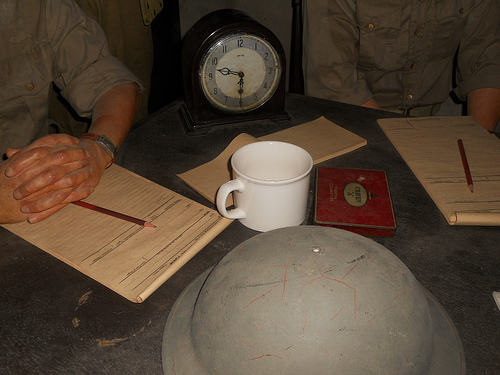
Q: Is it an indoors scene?
A: Yes, it is indoors.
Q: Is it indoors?
A: Yes, it is indoors.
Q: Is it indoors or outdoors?
A: It is indoors.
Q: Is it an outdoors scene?
A: No, it is indoors.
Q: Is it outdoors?
A: No, it is indoors.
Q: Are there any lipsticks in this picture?
A: No, there are no lipsticks.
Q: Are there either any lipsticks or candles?
A: No, there are no lipsticks or candles.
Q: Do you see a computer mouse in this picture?
A: No, there are no computer mice.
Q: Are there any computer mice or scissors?
A: No, there are no computer mice or scissors.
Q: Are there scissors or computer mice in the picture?
A: No, there are no computer mice or scissors.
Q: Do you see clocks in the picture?
A: Yes, there is a clock.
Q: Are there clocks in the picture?
A: Yes, there is a clock.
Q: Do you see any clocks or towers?
A: Yes, there is a clock.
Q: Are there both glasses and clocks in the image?
A: No, there is a clock but no glasses.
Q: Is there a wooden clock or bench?
A: Yes, there is a wood clock.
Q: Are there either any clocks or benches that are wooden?
A: Yes, the clock is wooden.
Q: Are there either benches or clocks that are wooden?
A: Yes, the clock is wooden.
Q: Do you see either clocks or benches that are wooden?
A: Yes, the clock is wooden.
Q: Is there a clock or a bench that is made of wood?
A: Yes, the clock is made of wood.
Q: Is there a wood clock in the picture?
A: Yes, there is a wood clock.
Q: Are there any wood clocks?
A: Yes, there is a wood clock.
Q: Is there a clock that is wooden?
A: Yes, there is a clock that is wooden.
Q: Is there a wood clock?
A: Yes, there is a clock that is made of wood.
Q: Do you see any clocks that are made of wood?
A: Yes, there is a clock that is made of wood.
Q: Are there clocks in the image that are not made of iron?
A: Yes, there is a clock that is made of wood.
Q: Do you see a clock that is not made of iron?
A: Yes, there is a clock that is made of wood.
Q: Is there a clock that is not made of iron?
A: Yes, there is a clock that is made of wood.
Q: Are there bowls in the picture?
A: No, there are no bowls.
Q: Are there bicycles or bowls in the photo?
A: No, there are no bowls or bicycles.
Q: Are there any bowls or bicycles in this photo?
A: No, there are no bowls or bicycles.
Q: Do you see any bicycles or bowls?
A: No, there are no bowls or bicycles.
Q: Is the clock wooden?
A: Yes, the clock is wooden.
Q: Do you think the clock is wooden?
A: Yes, the clock is wooden.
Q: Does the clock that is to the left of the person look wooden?
A: Yes, the clock is wooden.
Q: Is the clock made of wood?
A: Yes, the clock is made of wood.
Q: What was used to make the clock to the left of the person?
A: The clock is made of wood.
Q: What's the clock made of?
A: The clock is made of wood.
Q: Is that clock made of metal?
A: No, the clock is made of wood.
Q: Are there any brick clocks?
A: No, there is a clock but it is made of wood.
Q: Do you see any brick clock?
A: No, there is a clock but it is made of wood.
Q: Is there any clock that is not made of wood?
A: No, there is a clock but it is made of wood.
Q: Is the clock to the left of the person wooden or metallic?
A: The clock is wooden.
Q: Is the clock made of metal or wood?
A: The clock is made of wood.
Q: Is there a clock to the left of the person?
A: Yes, there is a clock to the left of the person.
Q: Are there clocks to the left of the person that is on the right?
A: Yes, there is a clock to the left of the person.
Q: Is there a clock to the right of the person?
A: No, the clock is to the left of the person.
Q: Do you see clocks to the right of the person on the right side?
A: No, the clock is to the left of the person.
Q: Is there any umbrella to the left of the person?
A: No, there is a clock to the left of the person.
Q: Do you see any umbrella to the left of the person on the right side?
A: No, there is a clock to the left of the person.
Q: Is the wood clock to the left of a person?
A: Yes, the clock is to the left of a person.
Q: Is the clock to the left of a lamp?
A: No, the clock is to the left of a person.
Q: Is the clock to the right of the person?
A: No, the clock is to the left of the person.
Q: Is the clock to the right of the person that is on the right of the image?
A: No, the clock is to the left of the person.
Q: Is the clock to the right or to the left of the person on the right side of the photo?
A: The clock is to the left of the person.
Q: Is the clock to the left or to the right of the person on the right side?
A: The clock is to the left of the person.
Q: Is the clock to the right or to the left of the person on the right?
A: The clock is to the left of the person.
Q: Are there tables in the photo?
A: Yes, there is a table.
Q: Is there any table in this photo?
A: Yes, there is a table.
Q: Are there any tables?
A: Yes, there is a table.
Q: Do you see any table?
A: Yes, there is a table.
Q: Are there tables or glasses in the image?
A: Yes, there is a table.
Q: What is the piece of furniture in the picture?
A: The piece of furniture is a table.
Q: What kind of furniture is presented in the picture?
A: The furniture is a table.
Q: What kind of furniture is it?
A: The piece of furniture is a table.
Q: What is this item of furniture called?
A: This is a table.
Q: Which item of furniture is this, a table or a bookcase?
A: This is a table.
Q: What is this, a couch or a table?
A: This is a table.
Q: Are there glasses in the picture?
A: No, there are no glasses.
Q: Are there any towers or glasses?
A: No, there are no glasses or towers.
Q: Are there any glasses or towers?
A: No, there are no glasses or towers.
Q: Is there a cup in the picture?
A: Yes, there is a cup.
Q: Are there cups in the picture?
A: Yes, there is a cup.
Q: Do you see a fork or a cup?
A: Yes, there is a cup.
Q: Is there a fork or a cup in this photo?
A: Yes, there is a cup.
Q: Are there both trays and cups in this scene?
A: No, there is a cup but no trays.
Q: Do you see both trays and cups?
A: No, there is a cup but no trays.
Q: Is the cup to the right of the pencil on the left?
A: Yes, the cup is to the right of the pencil.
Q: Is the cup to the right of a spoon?
A: No, the cup is to the right of the pencil.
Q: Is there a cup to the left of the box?
A: Yes, there is a cup to the left of the box.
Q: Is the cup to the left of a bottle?
A: No, the cup is to the left of the box.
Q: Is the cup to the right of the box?
A: No, the cup is to the left of the box.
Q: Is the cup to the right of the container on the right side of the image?
A: No, the cup is to the left of the box.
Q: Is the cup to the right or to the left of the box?
A: The cup is to the left of the box.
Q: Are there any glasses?
A: No, there are no glasses.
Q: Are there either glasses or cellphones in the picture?
A: No, there are no glasses or cellphones.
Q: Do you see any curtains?
A: No, there are no curtains.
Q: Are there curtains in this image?
A: No, there are no curtains.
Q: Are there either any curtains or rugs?
A: No, there are no curtains or rugs.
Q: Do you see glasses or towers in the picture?
A: No, there are no glasses or towers.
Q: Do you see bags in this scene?
A: No, there are no bags.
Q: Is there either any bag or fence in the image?
A: No, there are no bags or fences.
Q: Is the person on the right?
A: Yes, the person is on the right of the image.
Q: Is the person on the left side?
A: No, the person is on the right of the image.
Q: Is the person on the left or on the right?
A: The person is on the right of the image.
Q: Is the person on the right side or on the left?
A: The person is on the right of the image.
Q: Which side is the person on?
A: The person is on the right of the image.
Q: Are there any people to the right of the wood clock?
A: Yes, there is a person to the right of the clock.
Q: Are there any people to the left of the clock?
A: No, the person is to the right of the clock.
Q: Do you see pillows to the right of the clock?
A: No, there is a person to the right of the clock.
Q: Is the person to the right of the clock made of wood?
A: Yes, the person is to the right of the clock.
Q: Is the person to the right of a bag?
A: No, the person is to the right of the clock.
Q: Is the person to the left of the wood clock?
A: No, the person is to the right of the clock.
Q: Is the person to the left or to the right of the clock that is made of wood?
A: The person is to the right of the clock.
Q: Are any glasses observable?
A: No, there are no glasses.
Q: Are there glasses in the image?
A: No, there are no glasses.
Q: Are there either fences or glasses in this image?
A: No, there are no glasses or fences.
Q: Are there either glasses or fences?
A: No, there are no glasses or fences.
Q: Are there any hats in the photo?
A: Yes, there is a hat.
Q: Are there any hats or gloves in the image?
A: Yes, there is a hat.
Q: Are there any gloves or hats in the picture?
A: Yes, there is a hat.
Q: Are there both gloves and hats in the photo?
A: No, there is a hat but no gloves.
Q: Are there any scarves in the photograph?
A: No, there are no scarves.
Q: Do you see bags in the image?
A: No, there are no bags.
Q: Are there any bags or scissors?
A: No, there are no bags or scissors.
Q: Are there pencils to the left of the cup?
A: Yes, there is a pencil to the left of the cup.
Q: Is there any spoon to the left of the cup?
A: No, there is a pencil to the left of the cup.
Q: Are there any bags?
A: No, there are no bags.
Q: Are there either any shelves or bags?
A: No, there are no bags or shelves.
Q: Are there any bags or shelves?
A: No, there are no bags or shelves.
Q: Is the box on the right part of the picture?
A: Yes, the box is on the right of the image.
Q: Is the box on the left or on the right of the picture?
A: The box is on the right of the image.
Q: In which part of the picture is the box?
A: The box is on the right of the image.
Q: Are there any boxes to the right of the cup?
A: Yes, there is a box to the right of the cup.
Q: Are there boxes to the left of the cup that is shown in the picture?
A: No, the box is to the right of the cup.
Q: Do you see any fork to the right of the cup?
A: No, there is a box to the right of the cup.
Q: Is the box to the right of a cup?
A: Yes, the box is to the right of a cup.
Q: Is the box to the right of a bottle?
A: No, the box is to the right of a cup.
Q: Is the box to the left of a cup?
A: No, the box is to the right of a cup.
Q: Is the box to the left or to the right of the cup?
A: The box is to the right of the cup.